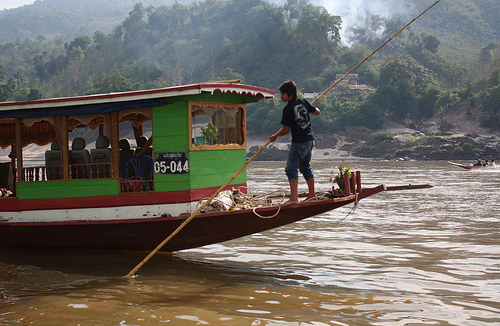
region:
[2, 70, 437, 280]
boat in the water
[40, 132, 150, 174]
seats on the boat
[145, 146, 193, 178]
numbers on the boat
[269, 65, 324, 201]
man standing on boat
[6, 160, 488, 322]
water with boats in it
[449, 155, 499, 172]
boat in the water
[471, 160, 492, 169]
people on the boat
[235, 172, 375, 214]
space for standing on boat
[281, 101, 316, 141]
shirt on the man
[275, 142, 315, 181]
pants on the man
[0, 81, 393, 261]
green and red river boat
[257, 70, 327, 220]
man steering river boat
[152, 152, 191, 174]
black sign with white numbers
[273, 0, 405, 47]
white smoke rising from the trees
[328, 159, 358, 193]
pot of flowers at the front of the boat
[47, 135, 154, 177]
seats for passengers on the boat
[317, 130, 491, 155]
very rocky river bank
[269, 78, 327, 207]
man wearing black shirt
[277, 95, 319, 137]
His shirt is black.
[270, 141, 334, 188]
The shorts are jeans.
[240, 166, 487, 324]
The water is calm.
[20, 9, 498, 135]
The trees are leafy.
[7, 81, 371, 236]
The boat is on the water.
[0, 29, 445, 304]
The boat is green.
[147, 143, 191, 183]
The sign is black.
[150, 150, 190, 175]
The numbers are white.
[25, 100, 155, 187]
The people are sitting on the boat.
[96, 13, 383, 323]
the kid is rowing the boat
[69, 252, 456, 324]
the water is brown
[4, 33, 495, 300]
the boat is in a river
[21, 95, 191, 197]
people are sitting inside the boat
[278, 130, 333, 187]
his pant legs are rolled up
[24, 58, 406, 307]
the boat is made of wood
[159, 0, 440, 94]
there is smoke in the trees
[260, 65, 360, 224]
he is wearing a black tee shirt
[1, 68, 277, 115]
the roof of the boat is red and white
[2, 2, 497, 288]
you can see two boats in the river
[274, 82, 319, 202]
a boy standing on the boat deck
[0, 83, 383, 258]
a small ferry boat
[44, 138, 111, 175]
seating inside the boat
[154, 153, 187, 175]
a boat number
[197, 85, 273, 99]
white trim on the boat's roof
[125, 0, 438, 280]
long stick to steer the boat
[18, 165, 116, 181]
wooden railing on the boat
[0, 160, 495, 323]
the water is dirty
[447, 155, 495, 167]
a boat in the water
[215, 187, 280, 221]
rope on the deck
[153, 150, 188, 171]
white numbers on a black sign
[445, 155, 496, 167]
small boat in the background with three people in it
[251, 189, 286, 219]
rope near the boy's foot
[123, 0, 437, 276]
long stick for steering the boat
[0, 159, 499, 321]
muddy brown water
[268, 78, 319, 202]
kid standing at the end of a boat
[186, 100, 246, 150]
yellow ornate frame